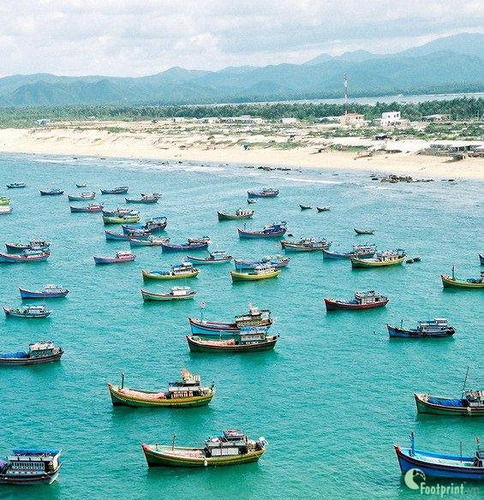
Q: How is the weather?
A: Cloudy.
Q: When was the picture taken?
A: Daytime.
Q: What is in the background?
A: Mountains.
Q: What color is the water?
A: Turquoise blue.